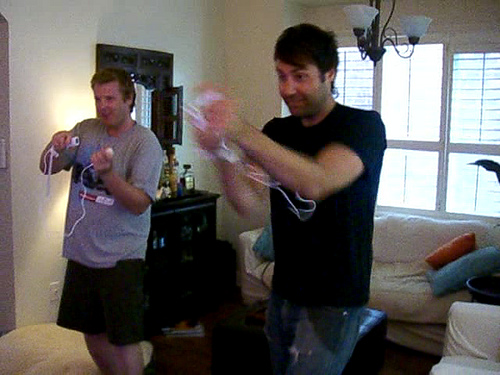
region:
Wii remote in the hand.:
[35, 126, 86, 161]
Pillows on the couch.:
[420, 226, 495, 292]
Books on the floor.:
[157, 310, 207, 335]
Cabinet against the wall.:
[90, 35, 225, 335]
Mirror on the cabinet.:
[127, 66, 152, 126]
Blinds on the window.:
[330, 40, 371, 111]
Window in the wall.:
[332, 38, 497, 214]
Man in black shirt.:
[200, 23, 392, 313]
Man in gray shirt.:
[40, 58, 167, 268]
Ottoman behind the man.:
[210, 290, 395, 368]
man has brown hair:
[75, 60, 146, 114]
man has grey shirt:
[63, 132, 131, 259]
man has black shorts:
[62, 257, 149, 346]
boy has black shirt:
[225, 110, 391, 317]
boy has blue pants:
[274, 292, 380, 367]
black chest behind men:
[143, 174, 214, 320]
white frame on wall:
[307, 60, 499, 220]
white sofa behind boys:
[377, 222, 482, 305]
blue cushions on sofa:
[434, 242, 493, 287]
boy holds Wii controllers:
[165, 77, 270, 202]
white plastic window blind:
[454, 55, 496, 62]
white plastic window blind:
[454, 65, 497, 72]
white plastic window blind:
[454, 75, 495, 82]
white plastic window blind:
[453, 85, 496, 91]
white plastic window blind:
[453, 94, 495, 102]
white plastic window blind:
[454, 103, 497, 111]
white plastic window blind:
[451, 115, 499, 121]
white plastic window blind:
[451, 124, 497, 134]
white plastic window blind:
[451, 134, 499, 143]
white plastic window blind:
[338, 57, 370, 61]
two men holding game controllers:
[33, 31, 352, 225]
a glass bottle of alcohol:
[179, 157, 201, 198]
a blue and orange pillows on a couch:
[414, 226, 487, 291]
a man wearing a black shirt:
[293, 100, 368, 174]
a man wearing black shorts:
[49, 258, 159, 335]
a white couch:
[373, 208, 439, 355]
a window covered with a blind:
[398, 24, 482, 198]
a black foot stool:
[352, 304, 396, 371]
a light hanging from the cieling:
[342, 7, 436, 64]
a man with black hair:
[259, 18, 341, 74]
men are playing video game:
[35, 11, 380, 351]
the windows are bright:
[353, 40, 480, 216]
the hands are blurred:
[180, 95, 255, 164]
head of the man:
[272, 24, 333, 111]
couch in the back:
[366, 175, 462, 316]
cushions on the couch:
[400, 218, 486, 296]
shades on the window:
[432, 43, 490, 140]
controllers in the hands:
[31, 126, 114, 190]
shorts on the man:
[12, 245, 141, 348]